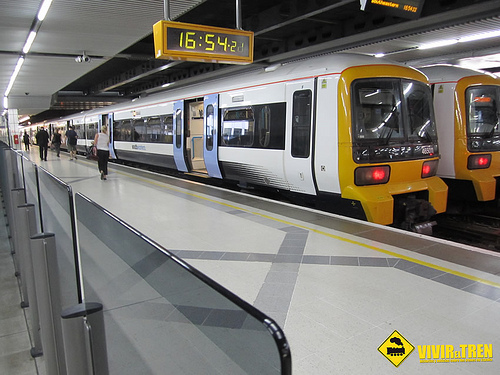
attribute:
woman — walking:
[93, 124, 110, 179]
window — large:
[352, 77, 439, 163]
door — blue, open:
[201, 91, 223, 183]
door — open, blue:
[170, 96, 187, 177]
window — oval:
[206, 103, 212, 153]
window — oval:
[175, 109, 180, 151]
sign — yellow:
[146, 15, 268, 72]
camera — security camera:
[74, 54, 89, 64]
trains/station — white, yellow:
[63, 35, 499, 310]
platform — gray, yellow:
[0, 128, 497, 373]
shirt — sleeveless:
[98, 131, 108, 151]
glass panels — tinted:
[16, 135, 303, 371]